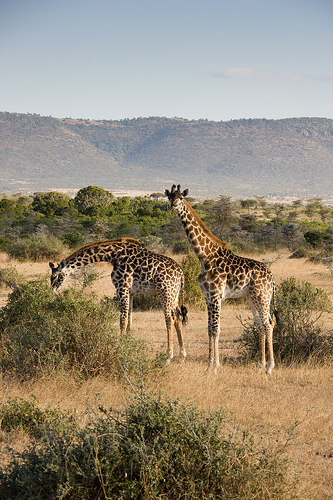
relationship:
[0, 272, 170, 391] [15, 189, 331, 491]
bush on top of prarie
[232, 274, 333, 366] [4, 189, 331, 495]
bush on top of prairie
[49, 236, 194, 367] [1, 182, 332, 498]
giraffe eating grass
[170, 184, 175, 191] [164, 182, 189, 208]
horn on top of head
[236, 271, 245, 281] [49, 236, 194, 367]
spots on giraffe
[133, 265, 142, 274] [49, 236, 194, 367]
spots on giraffe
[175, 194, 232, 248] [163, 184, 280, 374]
mane on giraffe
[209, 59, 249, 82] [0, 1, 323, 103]
cloud in sky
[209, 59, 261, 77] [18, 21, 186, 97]
cloud in blue sky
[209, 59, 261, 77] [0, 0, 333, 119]
cloud in blue sky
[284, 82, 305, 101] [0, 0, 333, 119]
white clouds in blue sky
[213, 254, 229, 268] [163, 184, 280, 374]
spots on giraffe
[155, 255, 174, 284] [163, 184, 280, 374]
spots on giraffe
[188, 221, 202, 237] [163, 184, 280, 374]
spots on giraffe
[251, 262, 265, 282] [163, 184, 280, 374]
spots on giraffe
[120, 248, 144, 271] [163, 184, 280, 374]
spots on giraffe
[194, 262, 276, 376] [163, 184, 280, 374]
legs of giraffe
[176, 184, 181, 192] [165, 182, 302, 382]
horn on top of giraffe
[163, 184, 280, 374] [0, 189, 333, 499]
giraffe on prairie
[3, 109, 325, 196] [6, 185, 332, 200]
hills on horizon line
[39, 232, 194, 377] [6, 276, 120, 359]
giraffe eat leaves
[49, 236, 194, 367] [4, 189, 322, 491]
giraffe stands on savannah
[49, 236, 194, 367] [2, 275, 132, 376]
giraffe feeds from bush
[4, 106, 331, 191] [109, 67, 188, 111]
hills meet sky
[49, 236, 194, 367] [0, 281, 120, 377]
giraffe eats bush